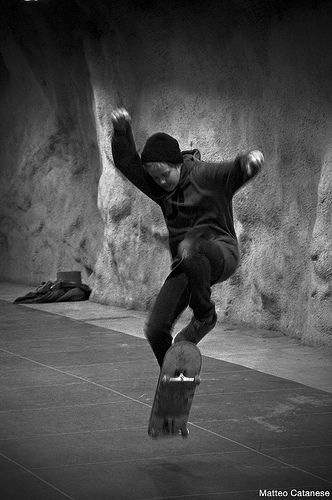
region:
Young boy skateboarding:
[69, 83, 319, 488]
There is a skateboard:
[122, 306, 242, 439]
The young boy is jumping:
[77, 126, 301, 484]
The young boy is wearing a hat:
[92, 95, 303, 487]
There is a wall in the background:
[25, 88, 329, 304]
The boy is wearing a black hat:
[79, 106, 288, 450]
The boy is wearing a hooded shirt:
[72, 89, 306, 293]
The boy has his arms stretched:
[73, 96, 311, 301]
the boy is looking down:
[101, 111, 287, 289]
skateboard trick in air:
[139, 340, 210, 456]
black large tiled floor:
[52, 353, 111, 453]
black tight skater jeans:
[129, 239, 229, 305]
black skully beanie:
[140, 122, 193, 180]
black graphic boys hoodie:
[135, 165, 246, 254]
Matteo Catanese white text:
[250, 484, 327, 496]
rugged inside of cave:
[47, 96, 105, 266]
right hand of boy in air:
[95, 91, 145, 171]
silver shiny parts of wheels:
[154, 373, 209, 394]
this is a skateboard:
[153, 345, 201, 437]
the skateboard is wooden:
[173, 347, 189, 361]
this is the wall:
[125, 23, 222, 107]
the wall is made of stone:
[263, 255, 303, 304]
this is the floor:
[28, 335, 84, 470]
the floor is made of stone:
[50, 359, 103, 464]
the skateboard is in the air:
[146, 340, 207, 441]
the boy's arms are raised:
[108, 108, 261, 190]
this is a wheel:
[161, 375, 169, 384]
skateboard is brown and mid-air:
[133, 333, 225, 453]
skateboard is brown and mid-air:
[141, 338, 204, 422]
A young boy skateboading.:
[28, 90, 304, 483]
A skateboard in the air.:
[141, 338, 214, 446]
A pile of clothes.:
[13, 262, 98, 308]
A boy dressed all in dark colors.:
[105, 108, 258, 354]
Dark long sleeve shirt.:
[111, 127, 242, 255]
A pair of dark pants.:
[146, 230, 239, 345]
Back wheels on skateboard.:
[141, 415, 199, 445]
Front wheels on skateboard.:
[151, 367, 207, 391]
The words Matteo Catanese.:
[250, 485, 330, 497]